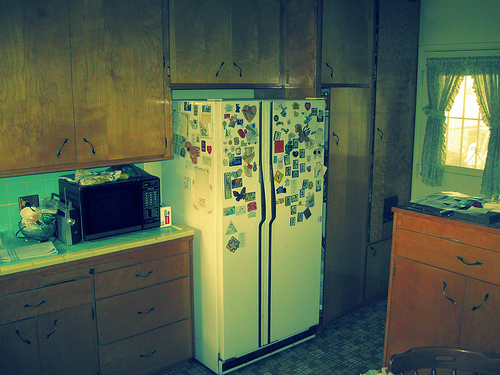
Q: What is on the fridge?
A: Magnets.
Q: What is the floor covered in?
A: Linoleum.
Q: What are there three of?
A: Drawers.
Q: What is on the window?
A: Curtains.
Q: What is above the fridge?
A: Cabinets.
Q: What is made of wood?
A: Cabinet.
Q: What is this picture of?
A: Kitchen.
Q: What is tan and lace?
A: Curtains.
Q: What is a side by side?
A: Refrigerator.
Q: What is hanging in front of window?
A: Curtains.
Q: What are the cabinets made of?
A: Wood.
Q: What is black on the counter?
A: Microwave.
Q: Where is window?
A: In door.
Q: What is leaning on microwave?
A: Radio.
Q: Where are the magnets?
A: The refrigerator.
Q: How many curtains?
A: Two.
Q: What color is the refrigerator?
A: White.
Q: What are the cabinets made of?
A: Wood.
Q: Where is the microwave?
A: The counter.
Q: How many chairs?
A: One.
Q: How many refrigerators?
A: One.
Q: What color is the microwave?
A: Black.